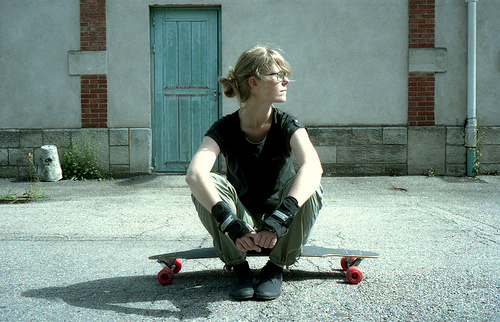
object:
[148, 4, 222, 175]
door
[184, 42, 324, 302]
woman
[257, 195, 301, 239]
wristbands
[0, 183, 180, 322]
cement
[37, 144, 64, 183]
stone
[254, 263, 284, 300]
shoes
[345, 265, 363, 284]
wheels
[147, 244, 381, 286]
skateboard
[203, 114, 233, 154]
sleeves